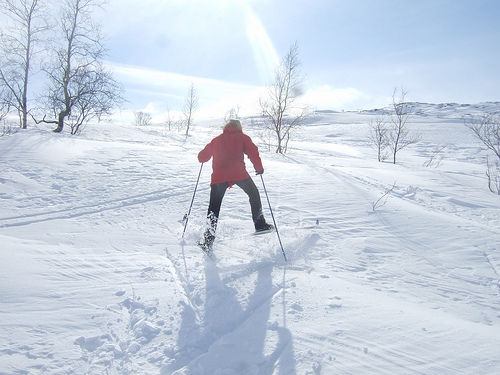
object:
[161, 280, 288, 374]
tracks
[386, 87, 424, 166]
tree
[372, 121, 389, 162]
tree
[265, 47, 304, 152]
tree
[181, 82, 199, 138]
tree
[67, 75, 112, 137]
tree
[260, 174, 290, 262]
pole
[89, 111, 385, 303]
ski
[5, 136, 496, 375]
snow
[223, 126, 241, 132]
hood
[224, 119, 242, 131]
head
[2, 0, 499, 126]
clouds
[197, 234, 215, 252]
foot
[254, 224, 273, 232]
foot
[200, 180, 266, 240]
pants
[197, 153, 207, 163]
elbow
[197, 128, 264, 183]
coat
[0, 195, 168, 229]
track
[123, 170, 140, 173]
footprint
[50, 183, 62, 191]
footprint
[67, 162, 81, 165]
footprint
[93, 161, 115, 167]
footprint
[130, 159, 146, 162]
footprint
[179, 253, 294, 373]
shadow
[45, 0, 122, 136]
tree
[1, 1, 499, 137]
background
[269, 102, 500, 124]
mountain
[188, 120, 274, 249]
person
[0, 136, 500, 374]
ground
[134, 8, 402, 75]
sky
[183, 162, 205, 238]
pole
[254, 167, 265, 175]
hand